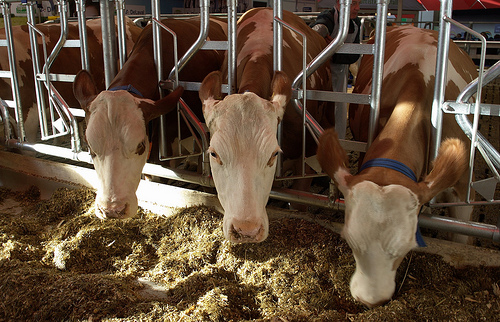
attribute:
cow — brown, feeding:
[67, 15, 206, 231]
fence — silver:
[5, 1, 490, 109]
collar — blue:
[360, 158, 420, 181]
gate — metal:
[21, 3, 194, 172]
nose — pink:
[223, 216, 273, 245]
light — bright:
[35, 89, 91, 157]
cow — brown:
[316, 126, 470, 307]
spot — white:
[212, 105, 286, 234]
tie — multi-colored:
[180, 97, 207, 146]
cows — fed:
[66, 28, 485, 314]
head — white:
[83, 93, 152, 217]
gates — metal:
[12, 6, 279, 175]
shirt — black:
[315, 14, 362, 61]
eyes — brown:
[87, 143, 150, 156]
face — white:
[208, 130, 280, 247]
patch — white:
[394, 105, 416, 120]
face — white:
[85, 122, 150, 220]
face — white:
[344, 225, 415, 306]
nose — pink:
[96, 199, 132, 218]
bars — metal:
[100, 3, 164, 57]